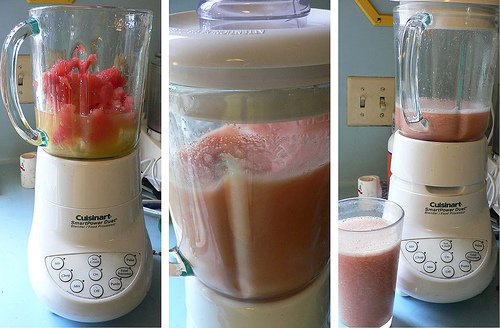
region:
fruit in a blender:
[2, 3, 160, 326]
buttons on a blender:
[44, 251, 149, 303]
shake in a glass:
[327, 183, 415, 327]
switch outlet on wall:
[347, 66, 399, 133]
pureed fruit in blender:
[163, 108, 332, 310]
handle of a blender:
[1, 10, 46, 155]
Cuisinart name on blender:
[422, 196, 477, 223]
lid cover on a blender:
[167, 0, 328, 92]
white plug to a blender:
[140, 152, 162, 198]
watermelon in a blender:
[40, 51, 134, 103]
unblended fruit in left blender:
[37, 52, 141, 159]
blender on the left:
[6, 10, 156, 323]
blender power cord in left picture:
[140, 156, 162, 213]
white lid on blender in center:
[170, 5, 337, 72]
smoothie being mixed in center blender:
[173, 125, 324, 301]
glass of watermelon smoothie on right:
[339, 200, 399, 326]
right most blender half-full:
[392, 7, 496, 299]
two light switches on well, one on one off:
[347, 77, 398, 124]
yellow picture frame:
[357, 0, 404, 27]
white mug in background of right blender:
[358, 172, 382, 204]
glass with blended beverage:
[334, 188, 412, 324]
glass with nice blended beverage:
[332, 190, 409, 322]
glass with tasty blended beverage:
[335, 183, 410, 320]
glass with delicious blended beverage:
[327, 188, 409, 324]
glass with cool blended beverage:
[327, 188, 411, 325]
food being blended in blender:
[157, 88, 322, 303]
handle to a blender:
[0, 6, 45, 160]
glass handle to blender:
[377, 3, 450, 149]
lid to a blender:
[158, 1, 335, 89]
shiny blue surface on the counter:
[16, 223, 25, 294]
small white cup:
[10, 154, 39, 191]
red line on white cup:
[9, 163, 28, 179]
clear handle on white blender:
[388, 12, 439, 145]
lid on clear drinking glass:
[345, 189, 412, 241]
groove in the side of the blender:
[173, 122, 272, 292]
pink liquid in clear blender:
[194, 151, 302, 290]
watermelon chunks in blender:
[40, 53, 109, 101]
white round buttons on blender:
[43, 239, 165, 298]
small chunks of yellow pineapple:
[34, 109, 133, 157]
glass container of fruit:
[14, 3, 168, 172]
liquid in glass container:
[9, 86, 144, 169]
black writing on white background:
[53, 206, 134, 240]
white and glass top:
[172, 4, 347, 139]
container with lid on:
[175, 16, 340, 298]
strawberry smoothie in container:
[167, 53, 354, 323]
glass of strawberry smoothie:
[336, 173, 430, 327]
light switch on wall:
[342, 70, 411, 138]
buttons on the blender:
[36, 161, 161, 323]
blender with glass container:
[392, 7, 498, 297]